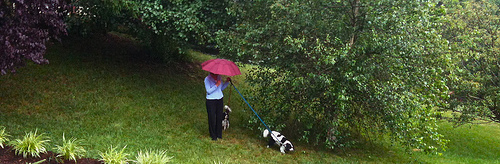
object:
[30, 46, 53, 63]
leaves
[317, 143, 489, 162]
grass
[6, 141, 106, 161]
dirt bed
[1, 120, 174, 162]
flowers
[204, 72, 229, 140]
woman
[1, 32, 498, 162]
grass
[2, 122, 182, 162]
plants row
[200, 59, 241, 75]
red umbrella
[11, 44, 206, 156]
grass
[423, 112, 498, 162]
grass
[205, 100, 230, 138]
pants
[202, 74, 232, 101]
shirt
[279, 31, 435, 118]
leaves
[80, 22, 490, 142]
tree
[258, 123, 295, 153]
dog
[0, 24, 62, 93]
flowers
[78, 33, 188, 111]
shade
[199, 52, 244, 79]
umbrella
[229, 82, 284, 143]
leash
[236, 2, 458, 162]
tree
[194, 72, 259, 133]
person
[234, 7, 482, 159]
bush